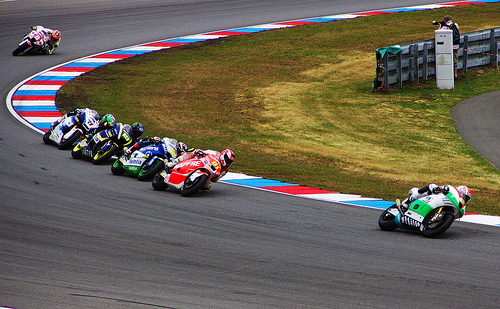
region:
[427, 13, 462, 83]
Man photographing motorcyclist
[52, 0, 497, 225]
Green grass curved along road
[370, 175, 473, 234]
First motorcycle is green and white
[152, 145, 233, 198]
Second motorcycle is red and white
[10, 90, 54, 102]
Red panel along road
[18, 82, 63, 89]
White panel along road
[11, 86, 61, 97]
Blue panel along road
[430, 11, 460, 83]
Photographer wearing pink button down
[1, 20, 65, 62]
Motorcyclist leaning close to the ground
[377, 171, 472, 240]
Motorcyclist riding motorcycle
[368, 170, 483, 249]
a motorbike on a road race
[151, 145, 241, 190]
a motorbike on a road race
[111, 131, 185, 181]
a motorbike on a road race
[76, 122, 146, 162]
a motorbike on a road race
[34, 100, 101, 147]
a motorbike on a road race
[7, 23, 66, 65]
a motorbike on a road race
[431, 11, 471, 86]
a man taking a video recording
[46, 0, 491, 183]
a patch of green grass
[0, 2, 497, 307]
the road is tarmacked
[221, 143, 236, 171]
the man is wearing a helmet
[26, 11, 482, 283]
7 motorcylces on the track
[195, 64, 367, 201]
the burnt grass on the infield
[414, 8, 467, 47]
man taking a photo on the side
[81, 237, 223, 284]
the concrete for the players to ride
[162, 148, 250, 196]
the red motorcylce behidn the gree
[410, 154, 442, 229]
the leader of the pack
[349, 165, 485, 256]
the green motorcycle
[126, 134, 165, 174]
the motorcycle in third place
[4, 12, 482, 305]
the race scene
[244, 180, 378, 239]
distance between first and 2nd place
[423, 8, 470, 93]
man taking photographs of the race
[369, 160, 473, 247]
leader of the race in green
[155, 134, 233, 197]
rider on a red bike with a red helmet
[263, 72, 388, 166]
patch of yellow grass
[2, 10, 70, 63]
orange helmet in last place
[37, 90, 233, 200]
four motorcyclists racing closely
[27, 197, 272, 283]
racetrack with marks on it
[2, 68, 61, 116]
red white and blue design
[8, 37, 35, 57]
rubber motorcycle tire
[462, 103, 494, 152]
pavement on the side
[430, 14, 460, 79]
a photographer with a professional camera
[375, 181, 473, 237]
a rider on a green motorcycle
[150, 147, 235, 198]
a rider with a red motorcycle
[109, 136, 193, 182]
a rider with a green and blue motorcycle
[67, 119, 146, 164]
a rider with a blue and yellow motorcycle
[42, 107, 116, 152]
a rider with a blue and white motorcycle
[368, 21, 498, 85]
a metal guard rail with a green banner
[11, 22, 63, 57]
a motorcycle rider with an orange helmet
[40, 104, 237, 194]
a set of four motorcyclists riding very close together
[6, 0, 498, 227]
a red white and blue track border